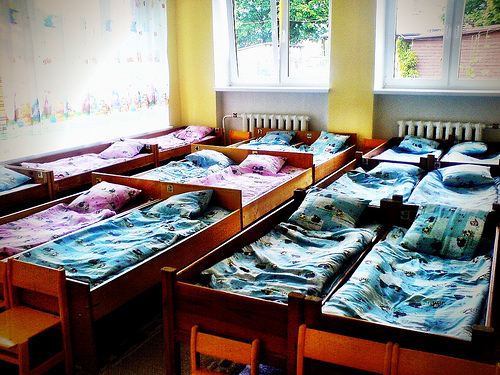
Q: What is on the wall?
A: Drawings.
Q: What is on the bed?
A: Bed sheet.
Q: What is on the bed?
A: Sheets.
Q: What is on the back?
A: Window.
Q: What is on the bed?
A: Pillow.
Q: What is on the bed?
A: Pillow.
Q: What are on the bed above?
A: Window.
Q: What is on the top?
A: Window.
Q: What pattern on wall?
A: Animals.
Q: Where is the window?
A: Left.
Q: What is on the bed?
A: Spreads.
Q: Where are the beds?
A: Room.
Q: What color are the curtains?
A: Yellow.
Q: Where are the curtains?
A: On windows.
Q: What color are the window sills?
A: White.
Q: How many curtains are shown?
A: Two.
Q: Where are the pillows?
A: The beds.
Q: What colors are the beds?
A: Blue and Pink.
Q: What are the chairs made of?
A: Wood.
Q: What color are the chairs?
A: Brown.